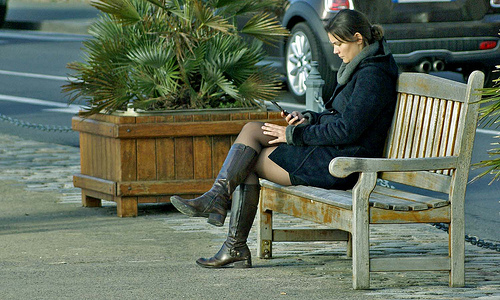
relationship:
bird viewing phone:
[170, 9, 399, 268] [271, 95, 296, 123]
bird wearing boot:
[170, 9, 399, 268] [167, 140, 262, 229]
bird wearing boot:
[170, 9, 399, 268] [194, 180, 261, 270]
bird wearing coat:
[170, 9, 399, 268] [269, 51, 397, 190]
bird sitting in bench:
[170, 9, 399, 268] [272, 60, 469, 288]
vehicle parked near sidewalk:
[207, 1, 497, 101] [0, 122, 480, 297]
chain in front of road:
[0, 112, 78, 132] [2, 28, 499, 247]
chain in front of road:
[429, 222, 499, 252] [2, 28, 499, 247]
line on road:
[2, 93, 99, 117] [2, 28, 499, 247]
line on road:
[2, 65, 499, 136] [2, 28, 499, 247]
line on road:
[0, 27, 100, 44] [2, 28, 499, 247]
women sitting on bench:
[291, 12, 392, 198] [272, 60, 469, 288]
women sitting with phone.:
[291, 12, 392, 198] [269, 97, 294, 119]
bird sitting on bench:
[170, 9, 399, 268] [253, 62, 483, 292]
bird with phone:
[170, 9, 399, 268] [272, 99, 295, 119]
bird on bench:
[170, 9, 399, 268] [165, 62, 497, 259]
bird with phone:
[170, 9, 399, 268] [262, 95, 299, 119]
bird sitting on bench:
[170, 9, 399, 268] [312, 77, 479, 207]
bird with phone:
[170, 9, 399, 268] [258, 84, 346, 138]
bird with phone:
[170, 9, 399, 268] [262, 84, 307, 125]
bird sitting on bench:
[170, 9, 399, 268] [253, 49, 498, 295]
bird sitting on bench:
[170, 9, 399, 268] [391, 65, 487, 286]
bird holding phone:
[170, 9, 399, 268] [268, 93, 287, 115]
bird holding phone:
[170, 9, 399, 268] [269, 99, 286, 117]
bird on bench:
[170, 9, 399, 268] [262, 66, 473, 295]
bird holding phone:
[170, 9, 399, 268] [266, 97, 306, 123]